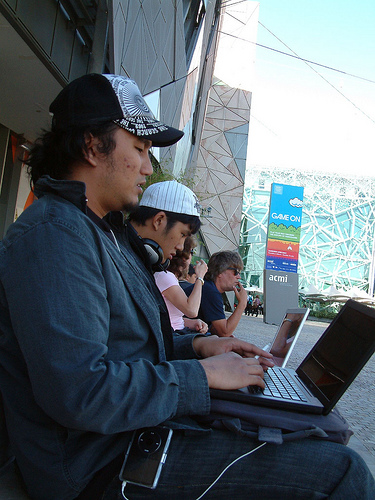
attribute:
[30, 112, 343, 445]
people — using, walking, playing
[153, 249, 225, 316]
man — holding, wearing, smoking, using, typing, touching, focused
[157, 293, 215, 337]
player — black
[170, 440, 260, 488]
cord — white, long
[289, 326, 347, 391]
laptop — black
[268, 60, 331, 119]
sky — white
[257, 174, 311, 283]
sign — large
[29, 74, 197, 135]
hat — black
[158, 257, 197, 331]
shirt — pink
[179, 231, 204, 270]
hair — long, brown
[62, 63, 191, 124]
cap — ball, black, white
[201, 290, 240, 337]
jacket — blue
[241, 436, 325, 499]
jean — blue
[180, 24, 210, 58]
building — glass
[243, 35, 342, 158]
day — sunny